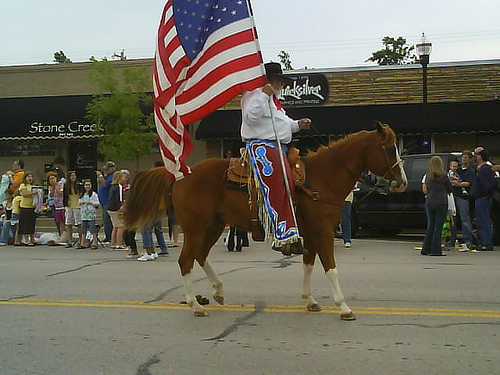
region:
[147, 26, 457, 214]
a man is carrying a flag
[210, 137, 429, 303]
the man is wearing colorful pants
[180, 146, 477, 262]
the man is on a brown horse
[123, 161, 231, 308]
the horse's tail is brown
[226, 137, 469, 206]
the man is on a saddle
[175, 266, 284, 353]
the horse has white hooves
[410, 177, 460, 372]
the woman is wearing dark jeans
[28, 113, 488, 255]
store fronts are facing the street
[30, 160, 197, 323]
the audience is standing by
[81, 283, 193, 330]
the street has yellow lines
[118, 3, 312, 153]
a american flag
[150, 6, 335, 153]
a guy holding an american flag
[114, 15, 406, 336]
a guy riding a brown and white horse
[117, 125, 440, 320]
a brown and white horse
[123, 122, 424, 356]
a horse walking in the road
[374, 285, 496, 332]
yellow double line in the road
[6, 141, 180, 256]
people standing on the sidewalk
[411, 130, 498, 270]
people standing in the road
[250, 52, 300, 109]
a guy with facial hair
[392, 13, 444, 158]
a black street light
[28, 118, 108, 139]
"Stone Creek" printed on awning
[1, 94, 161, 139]
black and white awning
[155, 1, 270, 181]
large American flag on pole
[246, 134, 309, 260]
red, white, and blue chaps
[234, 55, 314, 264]
man dressed as cowboy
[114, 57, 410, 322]
man riding horse on street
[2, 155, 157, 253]
crowd watching horse poop in parade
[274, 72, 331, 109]
black and white business sign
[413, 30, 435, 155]
street lamp behind car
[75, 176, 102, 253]
young girl watching parade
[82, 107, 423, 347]
The horse is brown and white.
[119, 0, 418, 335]
The man is riding a horse.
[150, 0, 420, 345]
The man is holding a flag.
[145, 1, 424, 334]
The man is wearing chaps.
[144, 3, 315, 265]
The flag is red, white and blue.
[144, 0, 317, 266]
The United States flag.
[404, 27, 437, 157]
The streetlamp is off.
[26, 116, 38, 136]
The lettering is white.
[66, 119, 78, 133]
The lettering is white.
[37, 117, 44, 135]
The lettering is white.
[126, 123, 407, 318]
brown and white horse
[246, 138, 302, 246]
blue and brown pants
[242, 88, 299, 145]
white button down shirt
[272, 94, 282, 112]
red tie on neck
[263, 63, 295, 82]
brown suede cowboy hat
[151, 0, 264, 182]
american flag on pole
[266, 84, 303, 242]
grey metal flag pole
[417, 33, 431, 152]
street lamp on pole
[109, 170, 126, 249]
person wearing blue jacket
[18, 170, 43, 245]
woman wearing yellow shirt